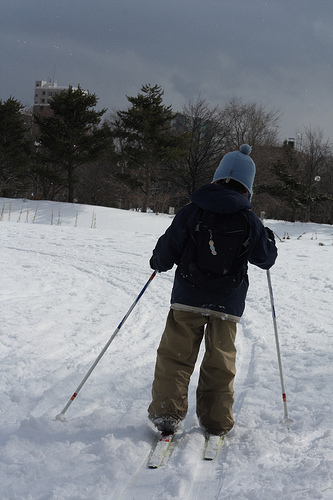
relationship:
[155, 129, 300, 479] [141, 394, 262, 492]
person has skis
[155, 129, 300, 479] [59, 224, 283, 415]
person holds poles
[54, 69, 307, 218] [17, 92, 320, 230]
building behind trees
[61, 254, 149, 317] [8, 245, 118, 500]
tracks in ground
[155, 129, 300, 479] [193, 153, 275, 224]
person has head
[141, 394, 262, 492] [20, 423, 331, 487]
skis in snow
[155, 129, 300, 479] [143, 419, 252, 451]
person has feet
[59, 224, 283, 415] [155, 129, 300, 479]
poles near person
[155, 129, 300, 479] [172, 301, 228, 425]
person has pants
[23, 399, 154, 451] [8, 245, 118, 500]
shadow on ground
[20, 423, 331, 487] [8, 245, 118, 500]
snow on ground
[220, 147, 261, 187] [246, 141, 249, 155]
hat has tip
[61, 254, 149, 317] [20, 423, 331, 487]
tracks in snow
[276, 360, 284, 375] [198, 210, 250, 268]
part of a hooker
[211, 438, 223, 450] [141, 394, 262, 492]
part of a skis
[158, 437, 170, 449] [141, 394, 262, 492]
part of a skis